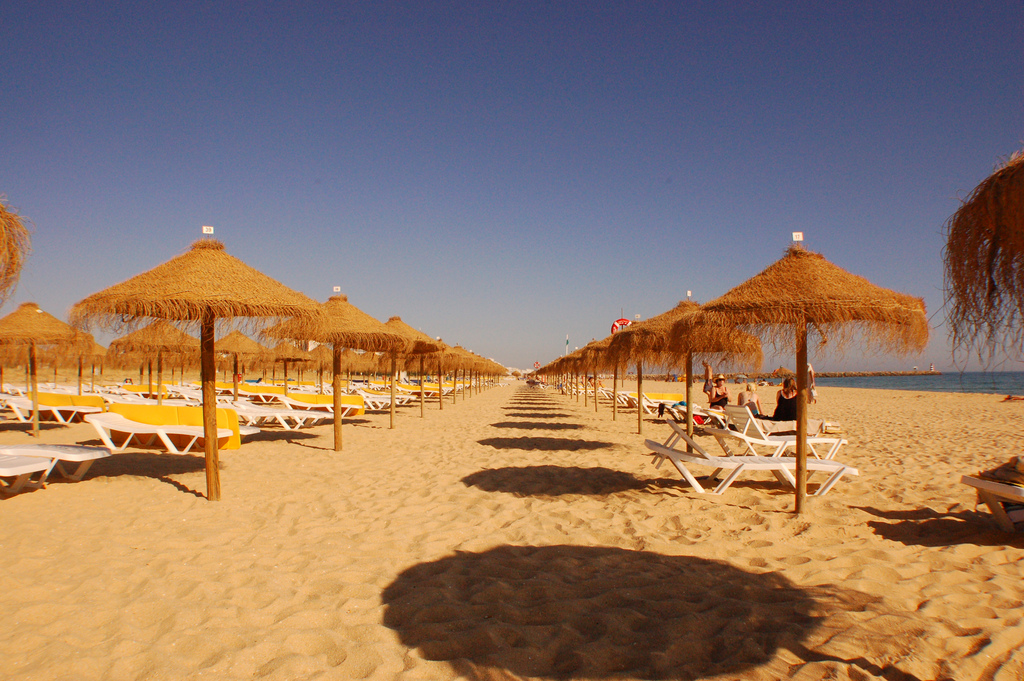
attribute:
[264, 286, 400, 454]
umbrella — tall, straw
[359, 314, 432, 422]
umbrella — tall, straw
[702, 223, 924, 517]
umbrella — tall, straw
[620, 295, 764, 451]
umbrella — straw, tall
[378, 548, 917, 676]
shadow — circular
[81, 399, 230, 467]
chair — white, lounge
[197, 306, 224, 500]
pole — brown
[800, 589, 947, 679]
lumps — sand , uneven 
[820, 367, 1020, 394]
water — blue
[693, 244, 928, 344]
umbrella — tall, grassy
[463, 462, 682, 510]
shadow — dark